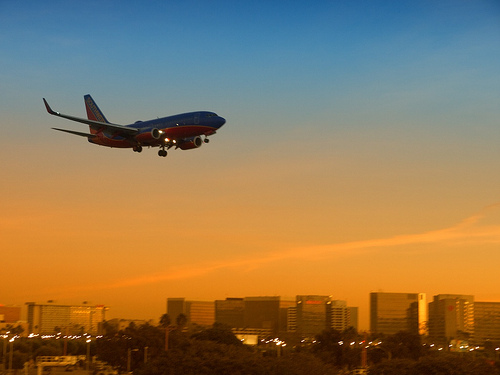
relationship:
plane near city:
[30, 75, 235, 176] [2, 293, 499, 369]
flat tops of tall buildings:
[26, 293, 498, 308] [25, 292, 498, 347]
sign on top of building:
[305, 298, 323, 306] [295, 291, 330, 345]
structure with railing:
[36, 354, 90, 371] [33, 354, 81, 364]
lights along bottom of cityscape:
[3, 328, 498, 354] [3, 290, 498, 352]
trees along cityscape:
[94, 316, 254, 365] [5, 282, 498, 354]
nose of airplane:
[212, 105, 228, 130] [29, 70, 241, 172]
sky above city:
[1, 1, 498, 328] [1, 283, 499, 372]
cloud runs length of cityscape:
[11, 204, 499, 298] [5, 282, 498, 354]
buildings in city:
[8, 292, 498, 341] [1, 283, 499, 372]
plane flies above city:
[36, 88, 228, 160] [3, 290, 498, 362]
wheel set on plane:
[202, 138, 212, 145] [36, 88, 228, 160]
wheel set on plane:
[154, 148, 170, 157] [36, 88, 228, 160]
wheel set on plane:
[131, 143, 148, 153] [36, 88, 228, 160]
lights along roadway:
[0, 325, 500, 355] [2, 338, 497, 355]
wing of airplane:
[56, 102, 97, 132] [37, 76, 239, 165]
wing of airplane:
[61, 127, 86, 142] [37, 76, 239, 165]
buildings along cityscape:
[24, 238, 499, 369] [1, 287, 499, 343]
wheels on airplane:
[133, 137, 175, 167] [42, 76, 227, 171]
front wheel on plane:
[202, 134, 209, 146] [36, 88, 228, 160]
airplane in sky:
[41, 90, 228, 159] [1, 1, 498, 328]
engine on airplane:
[139, 121, 184, 158] [42, 80, 230, 162]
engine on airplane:
[174, 131, 207, 154] [36, 89, 231, 163]